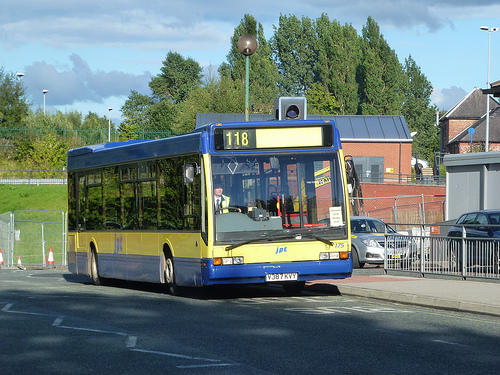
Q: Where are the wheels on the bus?
A: On the bottom.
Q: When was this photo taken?
A: In the daytime.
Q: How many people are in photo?
A: One.